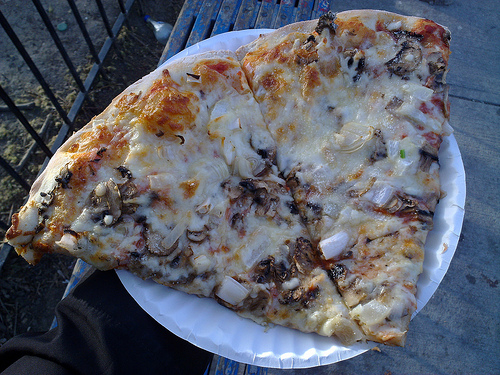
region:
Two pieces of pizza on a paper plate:
[5, 13, 447, 350]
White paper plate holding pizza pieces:
[111, 28, 464, 368]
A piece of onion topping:
[334, 122, 374, 152]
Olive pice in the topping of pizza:
[90, 180, 119, 224]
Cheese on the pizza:
[64, 63, 444, 348]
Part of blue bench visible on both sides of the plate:
[41, 1, 328, 373]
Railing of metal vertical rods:
[0, 1, 131, 261]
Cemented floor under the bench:
[310, 0, 499, 373]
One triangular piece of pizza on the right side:
[240, 8, 447, 343]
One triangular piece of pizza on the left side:
[6, 52, 362, 339]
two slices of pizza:
[12, 13, 453, 358]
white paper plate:
[125, 31, 467, 360]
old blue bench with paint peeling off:
[60, 2, 328, 372]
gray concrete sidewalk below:
[320, 4, 499, 374]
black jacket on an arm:
[5, 279, 210, 373]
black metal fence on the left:
[2, 0, 144, 270]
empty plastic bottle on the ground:
[145, 15, 172, 46]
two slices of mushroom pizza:
[17, 13, 452, 350]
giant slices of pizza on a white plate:
[15, 13, 459, 349]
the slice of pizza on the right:
[240, 12, 451, 347]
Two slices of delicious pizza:
[4, 4, 469, 367]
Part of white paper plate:
[186, 311, 231, 339]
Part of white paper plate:
[442, 182, 455, 254]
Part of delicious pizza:
[107, 187, 178, 232]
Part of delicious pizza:
[197, 222, 247, 266]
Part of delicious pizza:
[270, 267, 312, 304]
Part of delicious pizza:
[270, 50, 325, 96]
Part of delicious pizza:
[369, 96, 409, 163]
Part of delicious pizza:
[290, 130, 356, 180]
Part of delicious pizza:
[340, 233, 411, 288]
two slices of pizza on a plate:
[5, 5, 483, 370]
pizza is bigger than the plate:
[5, 6, 470, 355]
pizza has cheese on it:
[6, 7, 480, 355]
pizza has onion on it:
[8, 5, 458, 355]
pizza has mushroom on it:
[14, 11, 455, 353]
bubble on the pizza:
[132, 81, 202, 137]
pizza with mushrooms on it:
[13, 4, 460, 355]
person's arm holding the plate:
[14, 253, 240, 373]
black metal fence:
[3, 1, 150, 203]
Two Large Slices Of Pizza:
[1, 3, 497, 352]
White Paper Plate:
[98, 26, 467, 373]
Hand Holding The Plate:
[3, 214, 377, 374]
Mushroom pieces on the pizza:
[381, 29, 450, 91]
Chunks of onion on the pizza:
[313, 228, 357, 273]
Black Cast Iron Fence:
[0, 3, 160, 263]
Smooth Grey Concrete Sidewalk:
[240, 0, 497, 373]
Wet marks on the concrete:
[458, 260, 498, 298]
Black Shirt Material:
[0, 261, 213, 373]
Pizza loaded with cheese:
[20, 13, 458, 355]